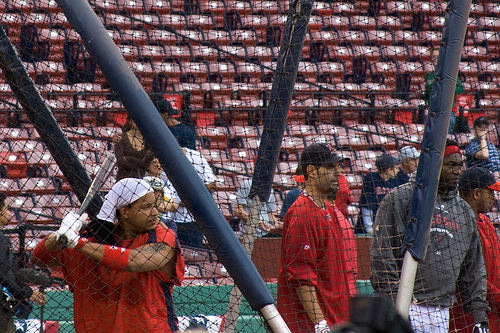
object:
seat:
[379, 40, 411, 59]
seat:
[321, 37, 355, 59]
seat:
[293, 55, 320, 78]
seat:
[202, 54, 237, 81]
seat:
[0, 147, 30, 177]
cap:
[419, 112, 499, 230]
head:
[111, 178, 156, 235]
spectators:
[357, 152, 404, 236]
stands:
[1, 1, 498, 283]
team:
[22, 153, 497, 331]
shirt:
[112, 132, 155, 179]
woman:
[111, 107, 153, 177]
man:
[276, 140, 359, 331]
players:
[454, 161, 499, 329]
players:
[374, 145, 486, 318]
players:
[277, 130, 363, 328]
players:
[23, 177, 208, 325]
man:
[289, 138, 353, 218]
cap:
[296, 141, 354, 173]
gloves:
[49, 208, 118, 279]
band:
[101, 245, 127, 270]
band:
[30, 235, 63, 262]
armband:
[101, 242, 131, 269]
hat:
[295, 124, 347, 172]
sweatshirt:
[369, 175, 486, 312]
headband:
[445, 146, 458, 153]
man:
[368, 132, 487, 321]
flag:
[179, 305, 226, 327]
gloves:
[48, 211, 94, 248]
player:
[26, 148, 189, 330]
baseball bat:
[50, 148, 121, 250]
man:
[271, 111, 393, 306]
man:
[23, 146, 190, 331]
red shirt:
[33, 224, 186, 330]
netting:
[1, 0, 498, 330]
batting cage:
[1, 0, 496, 331]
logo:
[429, 214, 461, 256]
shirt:
[275, 196, 380, 306]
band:
[443, 135, 465, 301]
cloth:
[92, 176, 153, 222]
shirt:
[109, 130, 157, 186]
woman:
[105, 104, 165, 186]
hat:
[150, 97, 182, 118]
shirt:
[274, 184, 359, 324]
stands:
[0, 3, 495, 238]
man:
[457, 168, 497, 331]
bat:
[55, 146, 116, 250]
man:
[374, 134, 488, 332]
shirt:
[31, 222, 189, 331]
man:
[33, 176, 183, 326]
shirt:
[450, 214, 499, 327]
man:
[450, 164, 496, 329]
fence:
[0, 0, 446, 325]